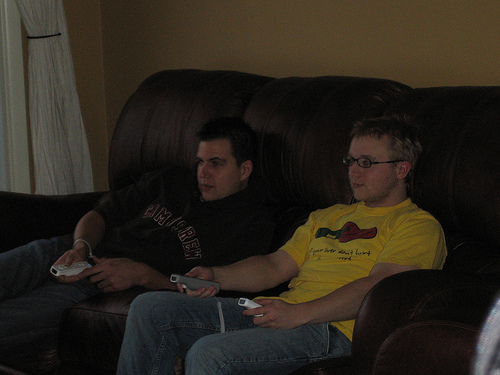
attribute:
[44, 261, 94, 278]
wii control — white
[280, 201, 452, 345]
t-shirt — yellow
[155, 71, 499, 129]
couch — large, leather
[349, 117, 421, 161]
hair — short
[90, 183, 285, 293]
shirt — red